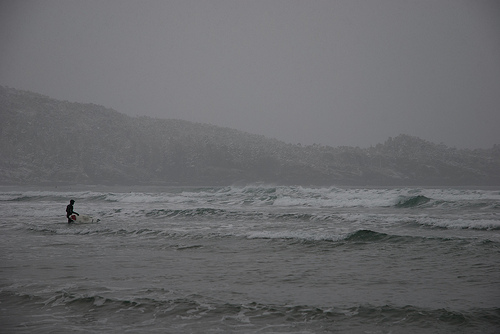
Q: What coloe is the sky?
A: Grey.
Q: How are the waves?
A: Choppy.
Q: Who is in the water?
A: Surfer.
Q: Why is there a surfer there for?
A: Waves.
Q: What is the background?
A: Hills.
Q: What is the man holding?
A: Surfboard.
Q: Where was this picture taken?
A: Shore.